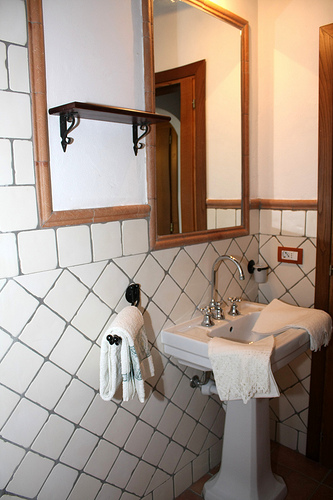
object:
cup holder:
[246, 258, 269, 283]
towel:
[99, 305, 156, 405]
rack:
[105, 282, 141, 346]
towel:
[251, 295, 333, 354]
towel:
[208, 335, 281, 405]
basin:
[206, 309, 288, 346]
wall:
[255, 0, 321, 455]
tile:
[17, 302, 69, 358]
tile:
[52, 375, 97, 426]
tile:
[27, 410, 77, 462]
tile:
[102, 406, 137, 450]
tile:
[16, 229, 58, 273]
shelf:
[47, 101, 171, 158]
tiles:
[142, 430, 171, 467]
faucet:
[204, 254, 245, 306]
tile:
[111, 252, 147, 281]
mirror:
[144, 0, 244, 240]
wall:
[1, 0, 257, 498]